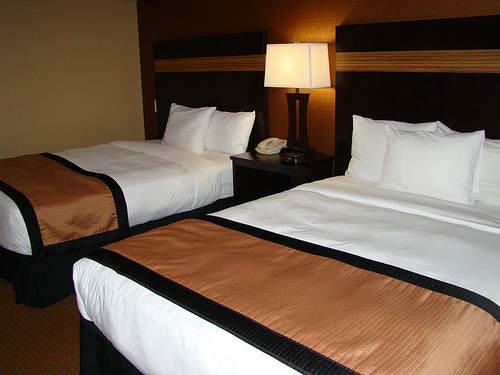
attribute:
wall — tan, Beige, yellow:
[0, 2, 147, 166]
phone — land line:
[254, 133, 288, 153]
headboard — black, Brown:
[149, 23, 273, 139]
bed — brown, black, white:
[10, 142, 134, 193]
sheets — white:
[322, 175, 499, 236]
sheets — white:
[201, 143, 234, 198]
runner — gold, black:
[103, 211, 495, 370]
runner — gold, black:
[2, 147, 123, 240]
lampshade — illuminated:
[252, 37, 338, 102]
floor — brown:
[1, 280, 93, 371]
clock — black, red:
[284, 149, 306, 168]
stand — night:
[227, 153, 344, 200]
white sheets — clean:
[3, 137, 238, 259]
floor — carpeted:
[1, 280, 81, 373]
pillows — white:
[165, 100, 250, 155]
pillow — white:
[377, 124, 484, 206]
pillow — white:
[344, 113, 436, 184]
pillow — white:
[434, 120, 499, 207]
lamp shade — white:
[245, 26, 356, 114]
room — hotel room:
[7, 31, 441, 358]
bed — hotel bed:
[9, 107, 232, 274]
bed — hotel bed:
[86, 113, 452, 348]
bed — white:
[1, 68, 273, 312]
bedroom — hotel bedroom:
[1, 1, 497, 371]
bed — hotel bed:
[72, 15, 499, 372]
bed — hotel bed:
[0, 29, 273, 302]